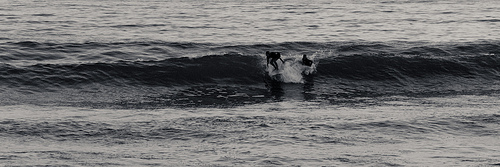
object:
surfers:
[265, 51, 281, 72]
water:
[1, 0, 500, 167]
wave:
[0, 42, 500, 105]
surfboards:
[269, 59, 295, 76]